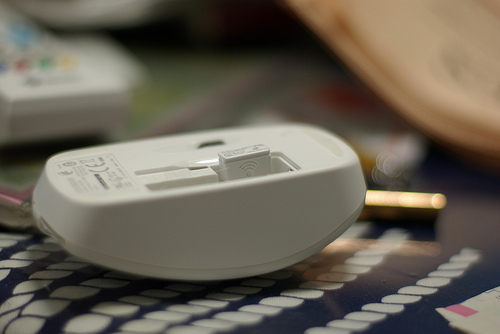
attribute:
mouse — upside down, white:
[28, 117, 368, 300]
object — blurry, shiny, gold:
[355, 181, 449, 223]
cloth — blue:
[11, 281, 499, 331]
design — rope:
[388, 245, 481, 319]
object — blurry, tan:
[288, 0, 499, 177]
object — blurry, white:
[0, 24, 160, 163]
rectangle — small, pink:
[438, 298, 483, 318]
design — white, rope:
[350, 240, 486, 326]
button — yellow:
[55, 51, 80, 71]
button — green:
[32, 51, 57, 69]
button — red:
[9, 51, 34, 72]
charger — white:
[27, 113, 368, 289]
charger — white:
[116, 131, 313, 207]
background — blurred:
[2, 4, 498, 145]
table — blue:
[390, 171, 499, 252]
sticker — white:
[57, 149, 135, 194]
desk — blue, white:
[419, 149, 499, 230]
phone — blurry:
[2, 13, 145, 147]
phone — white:
[4, 4, 147, 144]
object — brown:
[292, 0, 499, 150]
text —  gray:
[52, 148, 139, 200]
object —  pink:
[4, 178, 33, 199]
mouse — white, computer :
[30, 97, 367, 295]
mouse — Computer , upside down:
[19, 105, 393, 285]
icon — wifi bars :
[0, 29, 112, 109]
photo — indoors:
[3, 5, 484, 325]